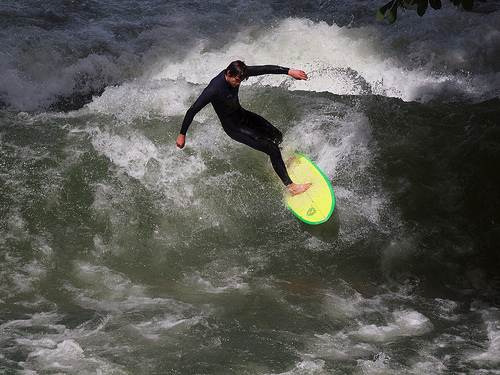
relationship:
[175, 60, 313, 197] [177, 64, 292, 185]
man wearing black suit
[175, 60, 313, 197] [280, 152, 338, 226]
man on surfboard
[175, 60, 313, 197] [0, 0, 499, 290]
man in waves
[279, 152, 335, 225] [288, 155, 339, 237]
green stripe on board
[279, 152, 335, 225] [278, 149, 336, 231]
green stripe on board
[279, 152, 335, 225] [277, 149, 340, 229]
green stripe on board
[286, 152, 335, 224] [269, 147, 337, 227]
green stripe on board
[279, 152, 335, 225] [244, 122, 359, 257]
green stripe on board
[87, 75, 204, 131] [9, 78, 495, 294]
cap of wave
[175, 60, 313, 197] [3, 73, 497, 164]
man riding curl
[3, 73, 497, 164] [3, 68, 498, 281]
curl of wave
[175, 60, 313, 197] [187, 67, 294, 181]
man in wetsuit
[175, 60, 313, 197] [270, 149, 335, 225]
man on board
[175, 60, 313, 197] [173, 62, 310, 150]
man with arms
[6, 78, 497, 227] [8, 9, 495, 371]
waves in ocean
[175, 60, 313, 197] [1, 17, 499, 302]
man on tall wave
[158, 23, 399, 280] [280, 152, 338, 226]
man on surfboard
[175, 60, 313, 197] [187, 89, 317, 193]
man wearing wetsuit